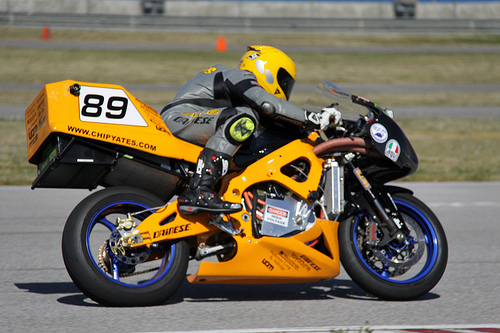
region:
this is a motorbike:
[48, 51, 481, 271]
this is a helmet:
[249, 33, 298, 88]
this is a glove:
[316, 96, 349, 129]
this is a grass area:
[431, 39, 497, 144]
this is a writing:
[78, 90, 135, 122]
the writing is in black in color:
[83, 95, 130, 120]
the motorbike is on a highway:
[71, 69, 428, 303]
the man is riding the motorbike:
[168, 46, 339, 159]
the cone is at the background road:
[205, 19, 236, 56]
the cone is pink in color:
[205, 27, 240, 59]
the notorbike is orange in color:
[183, 161, 375, 316]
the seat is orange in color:
[36, 67, 175, 175]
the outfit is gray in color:
[176, 53, 273, 171]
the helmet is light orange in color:
[241, 29, 322, 126]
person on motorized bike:
[21, 44, 468, 309]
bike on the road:
[18, 76, 435, 299]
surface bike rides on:
[6, 185, 496, 320]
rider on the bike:
[165, 34, 340, 214]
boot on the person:
[181, 150, 240, 215]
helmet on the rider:
[235, 41, 302, 99]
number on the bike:
[76, 85, 134, 126]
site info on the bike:
[64, 119, 164, 153]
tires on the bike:
[40, 188, 452, 305]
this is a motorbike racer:
[156, 31, 329, 269]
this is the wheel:
[366, 200, 445, 278]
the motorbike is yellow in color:
[264, 233, 321, 270]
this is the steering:
[326, 112, 341, 127]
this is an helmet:
[242, 49, 293, 77]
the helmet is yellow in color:
[256, 47, 282, 69]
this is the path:
[316, 291, 366, 329]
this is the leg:
[166, 150, 231, 222]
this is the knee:
[229, 111, 256, 142]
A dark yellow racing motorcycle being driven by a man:
[21, 80, 448, 303]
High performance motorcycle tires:
[64, 188, 447, 299]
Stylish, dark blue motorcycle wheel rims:
[350, 199, 437, 284]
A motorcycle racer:
[158, 44, 343, 212]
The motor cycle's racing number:
[81, 93, 128, 123]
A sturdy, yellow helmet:
[238, 43, 296, 103]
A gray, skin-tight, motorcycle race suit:
[160, 65, 307, 157]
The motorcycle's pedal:
[202, 210, 239, 233]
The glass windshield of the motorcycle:
[318, 83, 355, 104]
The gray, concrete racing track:
[2, 188, 497, 332]